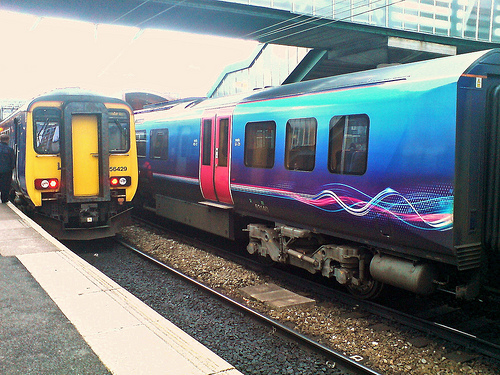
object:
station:
[1, 2, 498, 373]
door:
[214, 113, 234, 206]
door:
[198, 114, 218, 202]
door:
[72, 115, 99, 196]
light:
[110, 178, 118, 186]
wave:
[300, 179, 453, 232]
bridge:
[0, 0, 499, 68]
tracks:
[126, 209, 500, 359]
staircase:
[205, 44, 326, 101]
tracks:
[71, 239, 381, 375]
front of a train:
[25, 95, 137, 241]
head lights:
[49, 179, 57, 188]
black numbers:
[109, 167, 113, 171]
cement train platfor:
[0, 202, 243, 375]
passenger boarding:
[0, 129, 28, 215]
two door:
[198, 106, 233, 206]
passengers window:
[327, 114, 369, 175]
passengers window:
[149, 129, 169, 161]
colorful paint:
[230, 176, 457, 235]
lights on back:
[119, 177, 127, 185]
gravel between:
[183, 251, 226, 278]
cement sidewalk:
[0, 204, 242, 375]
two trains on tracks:
[0, 47, 500, 312]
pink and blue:
[191, 101, 288, 186]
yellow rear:
[25, 93, 138, 207]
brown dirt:
[149, 284, 190, 305]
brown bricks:
[12, 251, 102, 300]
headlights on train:
[40, 179, 49, 188]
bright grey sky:
[0, 16, 69, 82]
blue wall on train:
[229, 76, 458, 180]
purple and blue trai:
[132, 47, 500, 302]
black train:
[0, 94, 139, 242]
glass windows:
[243, 120, 275, 168]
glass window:
[283, 118, 316, 171]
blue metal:
[379, 186, 442, 213]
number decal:
[109, 166, 127, 171]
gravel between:
[117, 212, 177, 254]